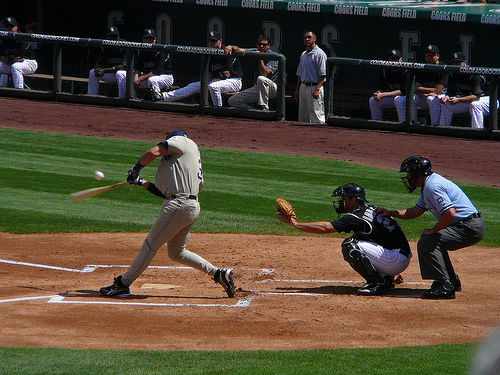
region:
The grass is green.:
[4, 124, 497, 264]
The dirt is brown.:
[2, 210, 497, 356]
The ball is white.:
[91, 167, 108, 180]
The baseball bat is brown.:
[64, 172, 136, 207]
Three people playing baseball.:
[92, 127, 487, 305]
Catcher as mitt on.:
[264, 188, 300, 228]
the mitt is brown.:
[263, 192, 302, 230]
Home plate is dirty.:
[138, 273, 182, 303]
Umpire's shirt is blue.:
[405, 161, 487, 233]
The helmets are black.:
[317, 146, 441, 217]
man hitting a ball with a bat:
[70, 128, 239, 298]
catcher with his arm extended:
[270, 180, 413, 294]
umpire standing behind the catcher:
[371, 152, 487, 302]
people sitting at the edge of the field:
[1, 12, 497, 134]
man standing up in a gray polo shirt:
[293, 31, 327, 124]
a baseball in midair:
[88, 165, 105, 184]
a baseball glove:
[272, 193, 297, 226]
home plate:
[140, 279, 182, 290]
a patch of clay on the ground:
[2, 224, 497, 351]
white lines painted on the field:
[1, 252, 436, 306]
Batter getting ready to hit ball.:
[67, 127, 263, 298]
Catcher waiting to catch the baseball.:
[272, 181, 412, 296]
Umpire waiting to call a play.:
[372, 146, 484, 303]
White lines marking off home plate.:
[5, 248, 442, 328]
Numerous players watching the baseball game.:
[0, 16, 495, 127]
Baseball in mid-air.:
[90, 170, 106, 181]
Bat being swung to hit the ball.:
[66, 177, 126, 193]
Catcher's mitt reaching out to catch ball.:
[273, 193, 293, 223]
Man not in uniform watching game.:
[291, 27, 326, 123]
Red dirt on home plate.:
[3, 213, 495, 348]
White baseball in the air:
[91, 170, 106, 182]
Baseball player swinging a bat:
[70, 125, 239, 302]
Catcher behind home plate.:
[272, 182, 412, 292]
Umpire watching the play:
[371, 156, 482, 318]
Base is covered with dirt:
[138, 282, 183, 290]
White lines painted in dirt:
[1, 250, 433, 310]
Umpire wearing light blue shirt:
[371, 155, 483, 310]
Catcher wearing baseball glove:
[272, 184, 415, 296]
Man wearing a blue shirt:
[293, 32, 333, 123]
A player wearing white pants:
[437, 53, 496, 127]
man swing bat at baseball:
[67, 126, 261, 328]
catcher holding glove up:
[248, 173, 435, 294]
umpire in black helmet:
[394, 134, 476, 296]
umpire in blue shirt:
[389, 119, 487, 339]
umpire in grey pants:
[394, 143, 493, 313]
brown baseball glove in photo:
[260, 188, 316, 253]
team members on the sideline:
[20, 16, 484, 163]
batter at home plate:
[44, 114, 275, 373]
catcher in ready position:
[263, 151, 433, 335]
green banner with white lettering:
[279, 3, 496, 42]